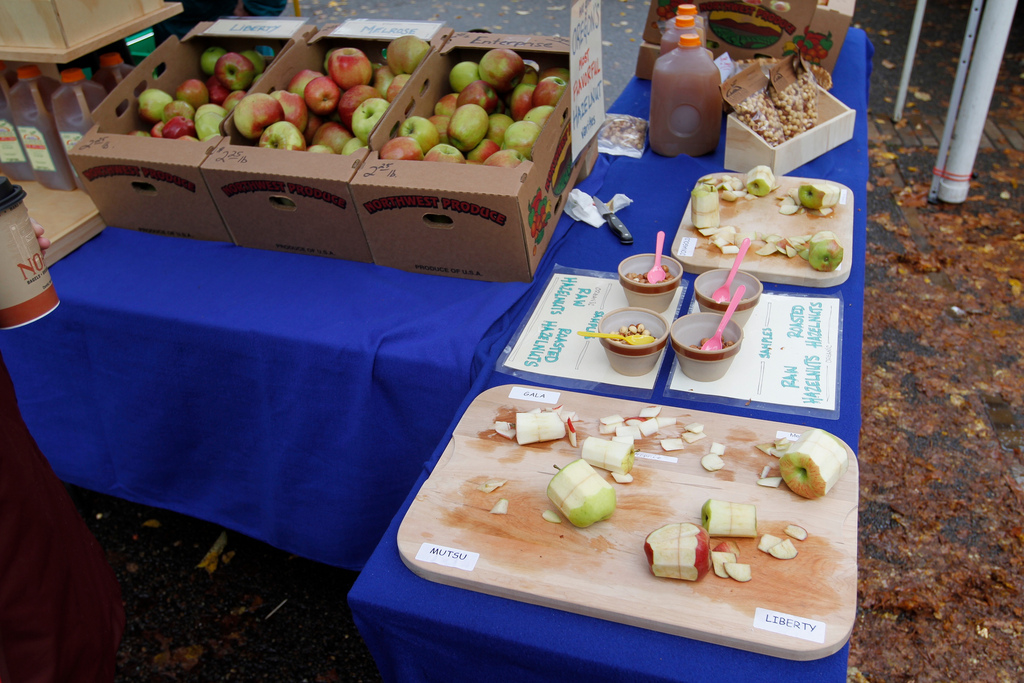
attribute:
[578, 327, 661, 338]
spoon — YELLOW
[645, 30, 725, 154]
jug — cider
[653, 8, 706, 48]
jug — cider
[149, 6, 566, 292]
apples — red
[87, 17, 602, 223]
apples — green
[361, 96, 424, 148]
apple — green, red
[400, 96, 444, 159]
apple — red, green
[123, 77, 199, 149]
apple — green, red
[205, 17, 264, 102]
apple — red, green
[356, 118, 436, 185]
apple — green, red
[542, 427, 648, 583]
apple — green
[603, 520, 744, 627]
apple — red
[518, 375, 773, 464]
apples — chopped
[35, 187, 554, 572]
cloth — blue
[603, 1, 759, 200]
jugs — apple cider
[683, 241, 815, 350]
spoon — pink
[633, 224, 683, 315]
spoon — pink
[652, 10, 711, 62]
lid — orange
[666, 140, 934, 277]
apples — green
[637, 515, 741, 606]
apple — red, white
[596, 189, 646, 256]
handle — black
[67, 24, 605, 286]
boxes — are brown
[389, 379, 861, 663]
board — is wooden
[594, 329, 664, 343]
spoon — is yellow 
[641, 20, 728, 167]
jug — is cider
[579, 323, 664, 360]
spoon — is yellow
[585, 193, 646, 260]
knife — is black handled